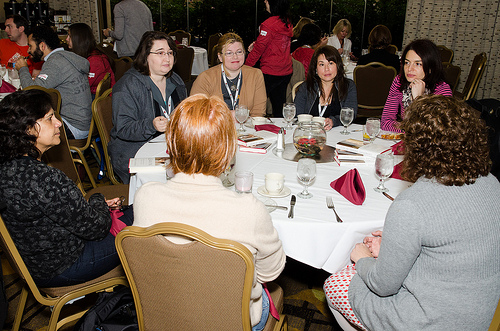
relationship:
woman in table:
[105, 30, 187, 178] [127, 110, 498, 301]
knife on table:
[285, 193, 297, 218] [306, 207, 324, 223]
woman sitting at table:
[384, 104, 498, 329] [127, 117, 462, 276]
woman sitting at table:
[372, 40, 462, 143] [118, 109, 436, 300]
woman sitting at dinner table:
[292, 42, 359, 119] [124, 110, 449, 272]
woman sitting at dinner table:
[186, 30, 266, 114] [134, 116, 413, 268]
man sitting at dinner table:
[6, 24, 98, 151] [146, 112, 469, 252]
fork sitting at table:
[322, 190, 351, 226] [123, 107, 493, 255]